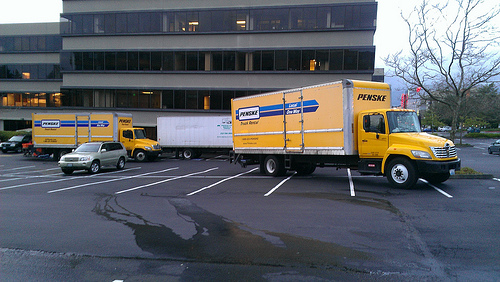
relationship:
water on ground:
[83, 187, 381, 278] [0, 148, 498, 279]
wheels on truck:
[258, 149, 414, 185] [227, 77, 467, 192]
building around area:
[2, 0, 387, 137] [1, 106, 464, 252]